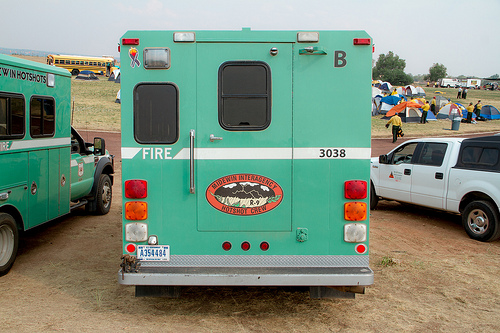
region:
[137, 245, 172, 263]
LICENSE PLATE ON THE BACK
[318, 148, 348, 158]
NUMBERS IN BLACK ON THE TRUCK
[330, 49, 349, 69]
BLACK B IS ON THE TRUCK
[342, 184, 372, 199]
RED LIGHT ON THE TRUCK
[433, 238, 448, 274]
DIRT IS ON THE GROUND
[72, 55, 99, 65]
SCHOOL BUS ACROSS THE FIELD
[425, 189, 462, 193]
WHITE TRUCK ON THE FIELD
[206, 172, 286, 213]
LOGO ON THE BACK OF TRUCK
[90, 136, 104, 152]
MIRROR STANDING OUT ON THE TRUCK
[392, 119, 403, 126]
MAN IS WEARING A YELLOW SHIRT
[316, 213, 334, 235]
part of a truck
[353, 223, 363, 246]
part of a light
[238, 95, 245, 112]
part of a window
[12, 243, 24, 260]
part of a wheel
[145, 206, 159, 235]
part of a truck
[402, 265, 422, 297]
part of the ground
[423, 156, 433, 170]
part of the window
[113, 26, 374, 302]
an aqua colored ambulance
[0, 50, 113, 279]
an aqua colored ambulance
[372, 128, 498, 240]
a white pick up truck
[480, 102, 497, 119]
a blue pop up tent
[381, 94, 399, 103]
a blue pop up tent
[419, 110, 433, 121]
a blue pop up tent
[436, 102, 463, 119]
a white and orange pop up tent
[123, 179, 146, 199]
a red brake light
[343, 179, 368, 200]
a red brake light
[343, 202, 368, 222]
a yellow turn signal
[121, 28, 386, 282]
back of ambulance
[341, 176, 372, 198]
tail light on ambulance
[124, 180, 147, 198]
tail light on ambulance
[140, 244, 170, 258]
license plate on ambulance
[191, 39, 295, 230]
door on ambulance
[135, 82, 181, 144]
window on ambulance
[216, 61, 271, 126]
door window on abulance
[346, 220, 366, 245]
reverse light on ambulance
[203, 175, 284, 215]
design on ambulance door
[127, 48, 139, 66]
design on ambulance door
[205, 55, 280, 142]
window on a car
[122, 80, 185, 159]
window on a car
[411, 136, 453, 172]
window on a car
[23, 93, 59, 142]
window on a car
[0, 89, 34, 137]
window on a car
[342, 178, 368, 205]
light on a car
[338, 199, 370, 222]
light on a car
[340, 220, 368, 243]
light on a car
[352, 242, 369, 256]
light on a car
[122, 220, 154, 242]
light on a car